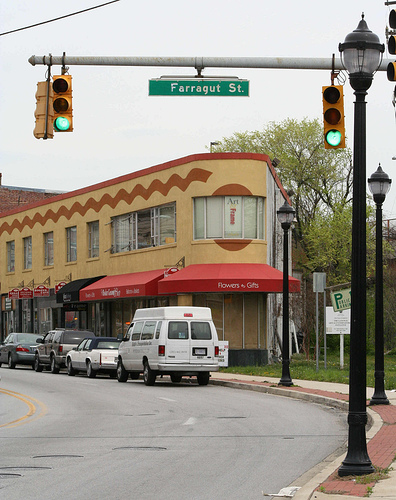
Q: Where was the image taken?
A: It was taken at the road.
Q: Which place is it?
A: It is a road.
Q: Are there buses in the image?
A: No, there are no buses.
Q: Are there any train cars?
A: No, there are no train cars.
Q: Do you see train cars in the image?
A: No, there are no train cars.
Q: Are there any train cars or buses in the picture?
A: No, there are no train cars or buses.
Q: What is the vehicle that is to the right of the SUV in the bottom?
A: The vehicle is a car.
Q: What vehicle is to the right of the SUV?
A: The vehicle is a car.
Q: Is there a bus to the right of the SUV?
A: No, there is a car to the right of the SUV.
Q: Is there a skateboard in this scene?
A: No, there are no skateboards.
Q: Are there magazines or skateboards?
A: No, there are no skateboards or magazines.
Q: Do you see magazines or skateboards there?
A: No, there are no skateboards or magazines.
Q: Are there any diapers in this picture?
A: No, there are no diapers.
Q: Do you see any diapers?
A: No, there are no diapers.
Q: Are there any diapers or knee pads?
A: No, there are no diapers or knee pads.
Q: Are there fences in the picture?
A: No, there are no fences.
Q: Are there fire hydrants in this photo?
A: No, there are no fire hydrants.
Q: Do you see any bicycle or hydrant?
A: No, there are no fire hydrants or bicycles.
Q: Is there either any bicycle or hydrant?
A: No, there are no fire hydrants or bicycles.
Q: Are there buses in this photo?
A: No, there are no buses.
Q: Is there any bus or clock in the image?
A: No, there are no buses or clocks.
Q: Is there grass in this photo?
A: Yes, there is grass.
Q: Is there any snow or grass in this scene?
A: Yes, there is grass.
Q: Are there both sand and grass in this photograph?
A: No, there is grass but no sand.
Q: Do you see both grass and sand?
A: No, there is grass but no sand.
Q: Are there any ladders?
A: No, there are no ladders.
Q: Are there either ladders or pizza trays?
A: No, there are no ladders or pizza trays.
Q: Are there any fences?
A: No, there are no fences.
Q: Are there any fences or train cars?
A: No, there are no fences or train cars.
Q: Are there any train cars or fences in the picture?
A: No, there are no fences or train cars.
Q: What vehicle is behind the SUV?
A: The vehicle is a car.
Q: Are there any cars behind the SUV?
A: Yes, there is a car behind the SUV.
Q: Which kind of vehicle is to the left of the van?
A: The vehicle is a car.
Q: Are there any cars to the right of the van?
A: No, the car is to the left of the van.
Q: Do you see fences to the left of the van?
A: No, there is a car to the left of the van.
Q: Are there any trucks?
A: No, there are no trucks.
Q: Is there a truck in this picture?
A: No, there are no trucks.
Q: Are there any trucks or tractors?
A: No, there are no trucks or tractors.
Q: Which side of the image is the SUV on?
A: The SUV is on the left of the image.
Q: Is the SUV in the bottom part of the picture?
A: Yes, the SUV is in the bottom of the image.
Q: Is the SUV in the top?
A: No, the SUV is in the bottom of the image.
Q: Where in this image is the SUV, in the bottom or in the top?
A: The SUV is in the bottom of the image.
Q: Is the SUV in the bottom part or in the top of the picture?
A: The SUV is in the bottom of the image.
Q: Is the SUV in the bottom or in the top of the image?
A: The SUV is in the bottom of the image.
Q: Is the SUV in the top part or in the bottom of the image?
A: The SUV is in the bottom of the image.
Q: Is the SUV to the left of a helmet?
A: No, the SUV is to the left of a car.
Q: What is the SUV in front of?
A: The SUV is in front of the car.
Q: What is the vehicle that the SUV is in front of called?
A: The vehicle is a car.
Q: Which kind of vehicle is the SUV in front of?
A: The SUV is in front of the car.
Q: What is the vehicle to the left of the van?
A: The vehicle is a SUV.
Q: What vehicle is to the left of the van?
A: The vehicle is a SUV.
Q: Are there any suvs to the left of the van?
A: Yes, there is a SUV to the left of the van.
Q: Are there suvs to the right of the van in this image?
A: No, the SUV is to the left of the van.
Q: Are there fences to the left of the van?
A: No, there is a SUV to the left of the van.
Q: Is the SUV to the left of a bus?
A: No, the SUV is to the left of a van.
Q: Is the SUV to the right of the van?
A: No, the SUV is to the left of the van.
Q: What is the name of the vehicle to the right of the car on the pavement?
A: The vehicle is a SUV.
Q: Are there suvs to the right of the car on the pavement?
A: Yes, there is a SUV to the right of the car.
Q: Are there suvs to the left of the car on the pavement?
A: No, the SUV is to the right of the car.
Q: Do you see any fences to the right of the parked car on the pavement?
A: No, there is a SUV to the right of the car.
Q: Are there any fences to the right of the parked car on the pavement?
A: No, there is a SUV to the right of the car.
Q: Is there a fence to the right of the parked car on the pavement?
A: No, there is a SUV to the right of the car.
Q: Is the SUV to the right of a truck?
A: No, the SUV is to the right of the car.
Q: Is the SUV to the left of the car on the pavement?
A: No, the SUV is to the right of the car.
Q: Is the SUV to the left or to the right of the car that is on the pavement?
A: The SUV is to the right of the car.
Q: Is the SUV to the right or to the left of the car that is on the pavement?
A: The SUV is to the right of the car.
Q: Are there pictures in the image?
A: No, there are no pictures.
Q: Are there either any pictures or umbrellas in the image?
A: No, there are no pictures or umbrellas.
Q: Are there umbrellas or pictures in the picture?
A: No, there are no pictures or umbrellas.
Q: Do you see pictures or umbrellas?
A: No, there are no pictures or umbrellas.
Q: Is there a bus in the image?
A: No, there are no buses.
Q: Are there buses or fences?
A: No, there are no buses or fences.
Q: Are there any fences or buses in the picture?
A: No, there are no buses or fences.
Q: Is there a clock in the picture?
A: No, there are no clocks.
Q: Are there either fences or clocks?
A: No, there are no clocks or fences.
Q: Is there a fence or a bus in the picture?
A: No, there are no fences or buses.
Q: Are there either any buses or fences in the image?
A: No, there are no fences or buses.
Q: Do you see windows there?
A: Yes, there is a window.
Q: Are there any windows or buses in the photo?
A: Yes, there is a window.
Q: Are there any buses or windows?
A: Yes, there is a window.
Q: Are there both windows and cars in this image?
A: Yes, there are both a window and a car.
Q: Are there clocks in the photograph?
A: No, there are no clocks.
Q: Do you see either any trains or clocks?
A: No, there are no clocks or trains.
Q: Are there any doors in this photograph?
A: Yes, there is a door.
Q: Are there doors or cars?
A: Yes, there is a door.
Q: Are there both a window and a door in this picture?
A: Yes, there are both a door and a window.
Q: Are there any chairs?
A: No, there are no chairs.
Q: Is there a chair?
A: No, there are no chairs.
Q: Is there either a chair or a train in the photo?
A: No, there are no chairs or trains.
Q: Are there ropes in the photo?
A: No, there are no ropes.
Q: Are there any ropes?
A: No, there are no ropes.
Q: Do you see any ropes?
A: No, there are no ropes.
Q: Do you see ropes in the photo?
A: No, there are no ropes.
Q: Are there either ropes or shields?
A: No, there are no ropes or shields.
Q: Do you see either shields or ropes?
A: No, there are no ropes or shields.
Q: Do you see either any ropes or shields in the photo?
A: No, there are no ropes or shields.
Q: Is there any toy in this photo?
A: No, there are no toys.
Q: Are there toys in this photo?
A: No, there are no toys.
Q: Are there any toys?
A: No, there are no toys.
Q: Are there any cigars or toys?
A: No, there are no toys or cigars.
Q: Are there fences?
A: No, there are no fences.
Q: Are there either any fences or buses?
A: No, there are no fences or buses.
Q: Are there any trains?
A: No, there are no trains.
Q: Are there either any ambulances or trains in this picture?
A: No, there are no trains or ambulances.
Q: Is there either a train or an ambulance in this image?
A: No, there are no trains or ambulances.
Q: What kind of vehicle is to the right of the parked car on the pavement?
A: The vehicle is a van.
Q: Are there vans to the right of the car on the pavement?
A: Yes, there is a van to the right of the car.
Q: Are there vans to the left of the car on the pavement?
A: No, the van is to the right of the car.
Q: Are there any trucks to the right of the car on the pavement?
A: No, there is a van to the right of the car.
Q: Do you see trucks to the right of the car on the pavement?
A: No, there is a van to the right of the car.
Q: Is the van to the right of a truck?
A: No, the van is to the right of the car.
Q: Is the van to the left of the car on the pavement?
A: No, the van is to the right of the car.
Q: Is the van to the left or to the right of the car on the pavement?
A: The van is to the right of the car.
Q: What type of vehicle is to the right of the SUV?
A: The vehicle is a van.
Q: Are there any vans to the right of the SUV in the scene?
A: Yes, there is a van to the right of the SUV.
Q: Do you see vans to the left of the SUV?
A: No, the van is to the right of the SUV.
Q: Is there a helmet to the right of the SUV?
A: No, there is a van to the right of the SUV.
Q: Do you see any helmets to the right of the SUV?
A: No, there is a van to the right of the SUV.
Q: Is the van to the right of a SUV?
A: Yes, the van is to the right of a SUV.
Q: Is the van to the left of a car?
A: No, the van is to the right of a car.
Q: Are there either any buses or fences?
A: No, there are no fences or buses.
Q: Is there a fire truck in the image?
A: No, there are no fire trucks.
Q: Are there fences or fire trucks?
A: No, there are no fire trucks or fences.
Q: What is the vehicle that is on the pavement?
A: The vehicle is a car.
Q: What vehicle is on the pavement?
A: The vehicle is a car.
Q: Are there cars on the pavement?
A: Yes, there is a car on the pavement.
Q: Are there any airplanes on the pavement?
A: No, there is a car on the pavement.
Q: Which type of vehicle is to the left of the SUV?
A: The vehicle is a car.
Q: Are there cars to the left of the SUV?
A: Yes, there is a car to the left of the SUV.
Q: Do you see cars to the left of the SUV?
A: Yes, there is a car to the left of the SUV.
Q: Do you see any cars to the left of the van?
A: Yes, there is a car to the left of the van.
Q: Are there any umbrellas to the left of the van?
A: No, there is a car to the left of the van.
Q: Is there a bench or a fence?
A: No, there are no fences or benches.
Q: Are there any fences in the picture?
A: No, there are no fences.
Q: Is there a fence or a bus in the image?
A: No, there are no fences or buses.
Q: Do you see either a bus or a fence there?
A: No, there are no fences or buses.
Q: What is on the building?
A: The sign is on the building.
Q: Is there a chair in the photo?
A: No, there are no chairs.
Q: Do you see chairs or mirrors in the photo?
A: No, there are no chairs or mirrors.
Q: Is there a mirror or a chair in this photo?
A: No, there are no chairs or mirrors.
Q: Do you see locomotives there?
A: No, there are no locomotives.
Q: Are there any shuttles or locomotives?
A: No, there are no locomotives or shuttles.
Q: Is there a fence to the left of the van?
A: No, there is a car to the left of the van.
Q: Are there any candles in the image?
A: No, there are no candles.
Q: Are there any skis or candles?
A: No, there are no candles or skis.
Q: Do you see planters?
A: No, there are no planters.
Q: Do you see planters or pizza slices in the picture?
A: No, there are no planters or pizza slices.